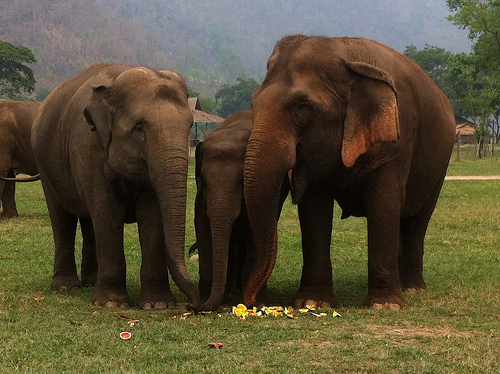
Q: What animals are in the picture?
A: Elephants.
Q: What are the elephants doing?
A: Eating.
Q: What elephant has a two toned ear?
A: The larger one.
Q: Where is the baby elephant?
A: Between the two larger elephants.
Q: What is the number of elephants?
A: 3.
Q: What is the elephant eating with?
A: Trunk.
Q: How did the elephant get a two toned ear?
A: Genetics.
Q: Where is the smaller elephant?
A: Between two larger elephants.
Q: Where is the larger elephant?
A: To the right of the smaller elephant.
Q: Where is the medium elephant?
A: To the left of the smaller elephant.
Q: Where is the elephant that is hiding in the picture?
A: Behind the left elephant.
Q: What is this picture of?
A: 3 elephants.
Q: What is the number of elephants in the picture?
A: There are a group of elephants.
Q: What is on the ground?
A: There is food on the ground.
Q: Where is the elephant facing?
A: The elephant is facing forward.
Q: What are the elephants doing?
A: Eating.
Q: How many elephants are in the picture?
A: Four.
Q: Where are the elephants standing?
A: On grass.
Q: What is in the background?
A: Mountains.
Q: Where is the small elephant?
A: Between the larger elephants.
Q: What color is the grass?
A: Green.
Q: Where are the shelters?
A: Behind the elephants.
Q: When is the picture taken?
A: Daytime.